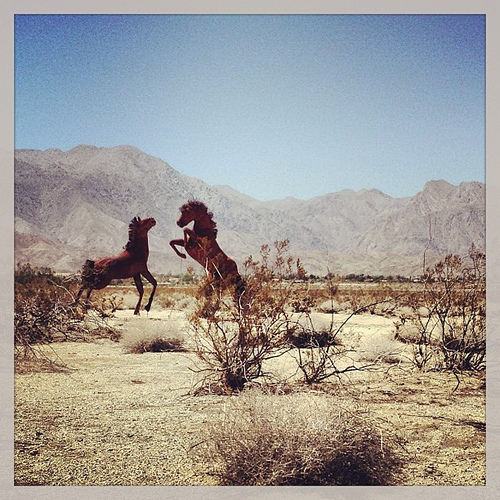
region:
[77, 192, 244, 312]
two horses are playing.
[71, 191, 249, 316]
the horses are brown.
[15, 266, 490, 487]
the ground is brown.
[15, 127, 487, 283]
mountains in the background.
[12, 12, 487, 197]
the sky is blue.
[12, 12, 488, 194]
the sky is clear.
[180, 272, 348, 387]
the bushes are dead.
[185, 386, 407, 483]
the weeds are brown.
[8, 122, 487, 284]
the mountains are brown.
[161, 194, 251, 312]
horse standing on hind legs.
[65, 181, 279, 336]
two horses in the dirt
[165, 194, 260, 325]
horse standing on its hind legs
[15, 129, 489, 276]
mountains in the distance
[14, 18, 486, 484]
horses in the wild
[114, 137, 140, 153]
highest point of the mountain range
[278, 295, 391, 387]
sticks jutting out of the ground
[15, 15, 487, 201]
light blue sky with no clouds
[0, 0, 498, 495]
gray border around the scene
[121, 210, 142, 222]
hair is sticking up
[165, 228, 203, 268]
front legs are bent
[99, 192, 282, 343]
these are two horses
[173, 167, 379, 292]
these are some mountains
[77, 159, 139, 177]
this is the highest peak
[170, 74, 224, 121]
there are no clouds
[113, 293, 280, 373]
there are no leaves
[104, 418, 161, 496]
the ground is parched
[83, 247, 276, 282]
the horses are brown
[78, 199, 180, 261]
this is a head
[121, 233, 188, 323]
this is a leg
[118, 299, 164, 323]
this is a hoof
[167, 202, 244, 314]
brown horse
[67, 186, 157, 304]
brown horse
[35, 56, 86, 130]
white clouds in blue sky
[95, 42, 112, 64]
white clouds in blue sky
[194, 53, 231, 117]
white clouds in blue sky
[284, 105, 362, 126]
white clouds in blue sky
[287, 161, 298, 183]
white clouds in blue sky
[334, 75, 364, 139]
white clouds in blue sky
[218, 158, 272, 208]
white clouds in blue sky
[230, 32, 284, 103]
white clouds in blue sky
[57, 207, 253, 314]
horses playing with one another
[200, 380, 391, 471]
small bush on the ground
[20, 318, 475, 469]
ground with twigs and grass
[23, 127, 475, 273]
mountains in the back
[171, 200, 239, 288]
horse on hind legs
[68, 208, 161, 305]
horse on all fours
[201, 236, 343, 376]
medium sized bush on land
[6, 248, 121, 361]
bush near the horses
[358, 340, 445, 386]
twigs on the ground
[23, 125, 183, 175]
peak of the mountain